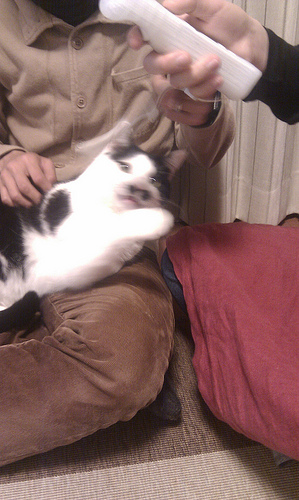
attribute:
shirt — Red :
[163, 216, 297, 458]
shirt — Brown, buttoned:
[0, 1, 234, 267]